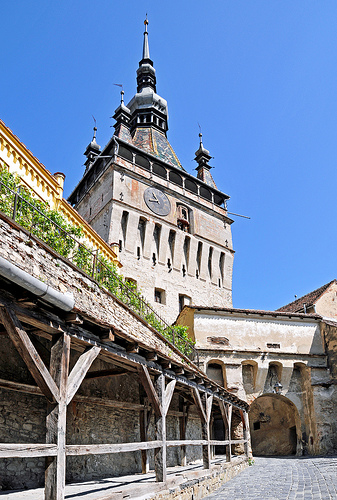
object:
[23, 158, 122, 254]
ledge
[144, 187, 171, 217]
clock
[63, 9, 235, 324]
old tower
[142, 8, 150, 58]
flag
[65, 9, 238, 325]
building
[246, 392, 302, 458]
entryway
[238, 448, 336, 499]
pathway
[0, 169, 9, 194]
leaves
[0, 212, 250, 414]
roof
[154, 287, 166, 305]
windows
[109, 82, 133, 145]
steeple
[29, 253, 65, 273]
shingles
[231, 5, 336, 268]
sky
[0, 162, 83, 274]
plants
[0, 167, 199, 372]
balcony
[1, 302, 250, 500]
beam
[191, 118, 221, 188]
steeple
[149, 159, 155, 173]
banister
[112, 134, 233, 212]
beams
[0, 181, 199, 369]
railing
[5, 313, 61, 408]
wood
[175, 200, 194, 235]
window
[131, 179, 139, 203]
stain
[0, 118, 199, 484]
building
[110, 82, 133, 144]
spire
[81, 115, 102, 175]
spire